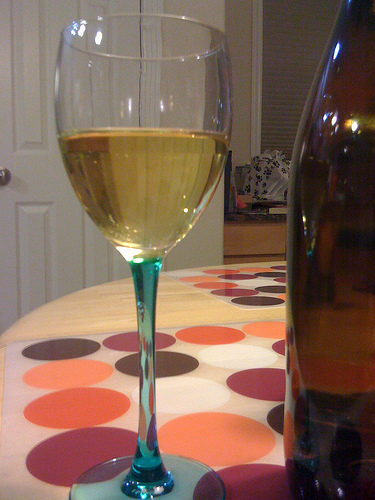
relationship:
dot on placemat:
[20, 335, 101, 359] [3, 313, 298, 498]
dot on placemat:
[116, 351, 199, 378] [3, 313, 298, 498]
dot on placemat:
[175, 326, 245, 346] [3, 313, 298, 498]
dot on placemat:
[227, 366, 290, 400] [3, 313, 298, 498]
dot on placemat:
[20, 335, 101, 359] [170, 259, 289, 309]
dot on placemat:
[201, 266, 238, 274] [170, 259, 289, 309]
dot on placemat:
[255, 284, 289, 294] [170, 259, 289, 309]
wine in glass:
[54, 124, 230, 265] [43, 12, 228, 500]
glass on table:
[43, 12, 228, 500] [2, 256, 374, 497]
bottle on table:
[283, 1, 374, 498] [2, 256, 374, 497]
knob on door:
[0, 165, 14, 186] [2, 0, 138, 337]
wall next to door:
[164, 0, 231, 264] [2, 0, 138, 337]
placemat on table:
[3, 313, 298, 498] [2, 256, 374, 497]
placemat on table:
[170, 259, 289, 309] [2, 256, 374, 497]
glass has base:
[43, 12, 228, 500] [66, 452, 227, 499]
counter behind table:
[222, 168, 286, 223] [2, 256, 374, 497]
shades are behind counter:
[261, 1, 352, 155] [222, 168, 286, 223]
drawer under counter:
[222, 222, 287, 256] [222, 168, 286, 223]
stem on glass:
[123, 262, 178, 493] [43, 12, 228, 500]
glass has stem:
[43, 12, 228, 500] [123, 262, 178, 493]